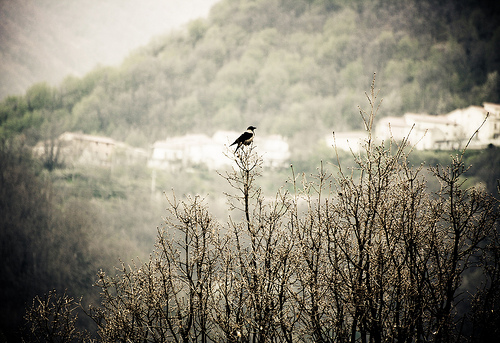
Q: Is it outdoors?
A: Yes, it is outdoors.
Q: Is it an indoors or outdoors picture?
A: It is outdoors.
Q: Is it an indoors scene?
A: No, it is outdoors.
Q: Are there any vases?
A: No, there are no vases.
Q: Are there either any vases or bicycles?
A: No, there are no vases or bicycles.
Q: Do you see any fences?
A: No, there are no fences.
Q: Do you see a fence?
A: No, there are no fences.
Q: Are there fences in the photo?
A: No, there are no fences.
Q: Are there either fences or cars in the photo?
A: No, there are no fences or cars.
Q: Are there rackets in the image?
A: No, there are no rackets.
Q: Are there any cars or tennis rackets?
A: No, there are no tennis rackets or cars.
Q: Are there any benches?
A: No, there are no benches.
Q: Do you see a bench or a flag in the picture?
A: No, there are no benches or flags.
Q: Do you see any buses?
A: No, there are no buses.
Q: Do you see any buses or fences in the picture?
A: No, there are no buses or fences.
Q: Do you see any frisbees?
A: No, there are no frisbees.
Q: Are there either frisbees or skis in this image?
A: No, there are no frisbees or skis.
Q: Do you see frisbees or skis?
A: No, there are no frisbees or skis.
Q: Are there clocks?
A: No, there are no clocks.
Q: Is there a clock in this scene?
A: No, there are no clocks.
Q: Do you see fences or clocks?
A: No, there are no clocks or fences.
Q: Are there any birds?
A: Yes, there is a bird.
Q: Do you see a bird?
A: Yes, there is a bird.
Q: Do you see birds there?
A: Yes, there is a bird.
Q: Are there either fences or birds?
A: Yes, there is a bird.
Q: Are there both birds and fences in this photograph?
A: No, there is a bird but no fences.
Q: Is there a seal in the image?
A: No, there are no seals.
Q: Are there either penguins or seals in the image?
A: No, there are no seals or penguins.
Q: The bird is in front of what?
A: The bird is in front of the building.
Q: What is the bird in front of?
A: The bird is in front of the building.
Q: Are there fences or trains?
A: No, there are no fences or trains.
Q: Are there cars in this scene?
A: No, there are no cars.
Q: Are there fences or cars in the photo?
A: No, there are no cars or fences.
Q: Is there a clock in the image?
A: No, there are no clocks.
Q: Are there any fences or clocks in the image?
A: No, there are no clocks or fences.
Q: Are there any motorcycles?
A: No, there are no motorcycles.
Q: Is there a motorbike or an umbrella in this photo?
A: No, there are no motorcycles or umbrellas.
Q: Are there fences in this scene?
A: No, there are no fences.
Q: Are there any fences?
A: No, there are no fences.